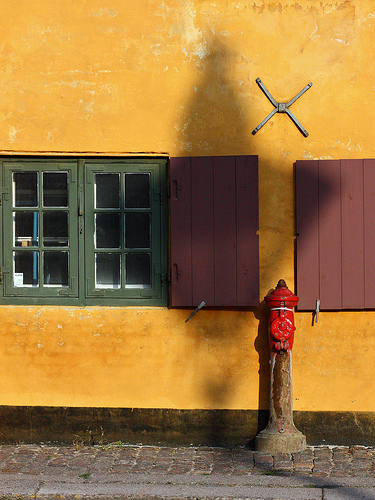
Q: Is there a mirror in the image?
A: No, there are no mirrors.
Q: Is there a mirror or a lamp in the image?
A: No, there are no mirrors or lamps.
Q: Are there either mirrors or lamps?
A: No, there are no mirrors or lamps.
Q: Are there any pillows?
A: No, there are no pillows.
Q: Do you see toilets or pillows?
A: No, there are no pillows or toilets.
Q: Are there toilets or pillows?
A: No, there are no pillows or toilets.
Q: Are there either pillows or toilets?
A: No, there are no pillows or toilets.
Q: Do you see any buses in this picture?
A: No, there are no buses.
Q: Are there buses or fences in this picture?
A: No, there are no buses or fences.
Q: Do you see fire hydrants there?
A: Yes, there is a fire hydrant.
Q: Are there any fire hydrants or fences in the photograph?
A: Yes, there is a fire hydrant.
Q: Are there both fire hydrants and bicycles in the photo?
A: No, there is a fire hydrant but no bicycles.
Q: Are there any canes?
A: No, there are no canes.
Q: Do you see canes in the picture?
A: No, there are no canes.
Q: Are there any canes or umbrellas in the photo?
A: No, there are no canes or umbrellas.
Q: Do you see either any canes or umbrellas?
A: No, there are no canes or umbrellas.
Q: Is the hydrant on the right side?
A: Yes, the hydrant is on the right of the image.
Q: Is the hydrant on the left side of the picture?
A: No, the hydrant is on the right of the image.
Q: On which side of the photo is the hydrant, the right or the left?
A: The hydrant is on the right of the image.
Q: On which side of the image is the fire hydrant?
A: The fire hydrant is on the right of the image.